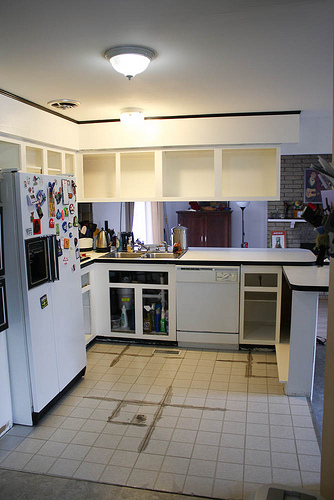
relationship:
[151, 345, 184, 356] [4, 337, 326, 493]
vent in floor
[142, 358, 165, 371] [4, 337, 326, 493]
tile on floor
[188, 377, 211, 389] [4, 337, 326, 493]
tile on floor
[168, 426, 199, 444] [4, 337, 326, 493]
tile on floor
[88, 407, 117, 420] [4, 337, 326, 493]
tile on floor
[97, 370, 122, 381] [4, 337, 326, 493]
tile on floor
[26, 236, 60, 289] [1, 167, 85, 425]
drink station on fridge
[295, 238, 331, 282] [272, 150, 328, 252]
fireplace on wall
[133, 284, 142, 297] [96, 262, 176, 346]
handles on cabinet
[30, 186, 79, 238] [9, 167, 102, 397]
magnets on fridge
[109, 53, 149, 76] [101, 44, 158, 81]
bulb on fixture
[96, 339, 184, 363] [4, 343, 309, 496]
repaired grout on floor tiles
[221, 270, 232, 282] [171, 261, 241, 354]
knob on dishwasher